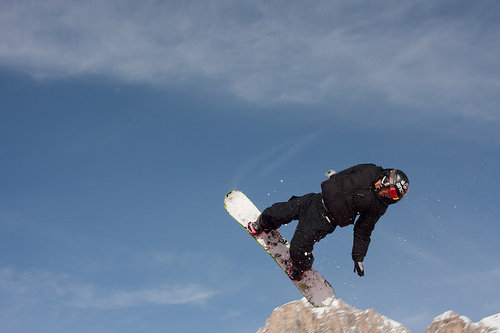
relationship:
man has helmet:
[248, 160, 411, 278] [378, 168, 411, 201]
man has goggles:
[248, 160, 411, 278] [387, 165, 401, 201]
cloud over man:
[2, 3, 498, 129] [248, 160, 411, 278]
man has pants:
[248, 160, 411, 278] [256, 192, 340, 278]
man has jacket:
[248, 160, 411, 278] [318, 161, 386, 264]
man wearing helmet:
[248, 160, 411, 278] [378, 168, 411, 201]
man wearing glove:
[248, 160, 411, 278] [352, 259, 366, 276]